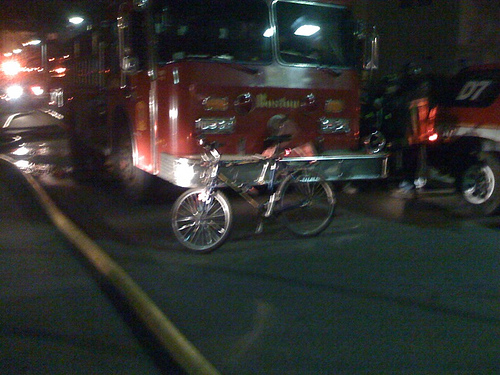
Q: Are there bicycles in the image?
A: Yes, there is a bicycle.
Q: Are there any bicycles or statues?
A: Yes, there is a bicycle.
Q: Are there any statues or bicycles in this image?
A: Yes, there is a bicycle.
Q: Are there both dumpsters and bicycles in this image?
A: No, there is a bicycle but no dumpsters.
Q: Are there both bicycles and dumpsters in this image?
A: No, there is a bicycle but no dumpsters.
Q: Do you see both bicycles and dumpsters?
A: No, there is a bicycle but no dumpsters.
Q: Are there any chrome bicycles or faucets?
A: Yes, there is a chrome bicycle.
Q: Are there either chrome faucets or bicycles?
A: Yes, there is a chrome bicycle.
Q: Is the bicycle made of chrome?
A: Yes, the bicycle is made of chrome.